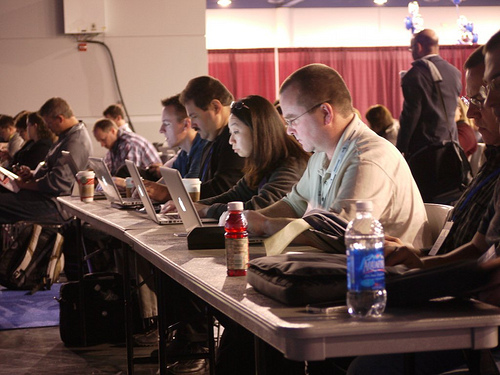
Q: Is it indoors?
A: Yes, it is indoors.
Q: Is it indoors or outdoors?
A: It is indoors.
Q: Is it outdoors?
A: No, it is indoors.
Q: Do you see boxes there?
A: No, there are no boxes.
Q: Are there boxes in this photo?
A: No, there are no boxes.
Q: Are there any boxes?
A: No, there are no boxes.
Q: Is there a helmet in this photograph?
A: No, there are no helmets.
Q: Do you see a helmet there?
A: No, there are no helmets.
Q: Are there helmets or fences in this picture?
A: No, there are no helmets or fences.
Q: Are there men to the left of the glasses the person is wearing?
A: Yes, there is a man to the left of the glasses.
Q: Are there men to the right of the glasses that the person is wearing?
A: No, the man is to the left of the glasses.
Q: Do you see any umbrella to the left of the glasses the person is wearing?
A: No, there is a man to the left of the glasses.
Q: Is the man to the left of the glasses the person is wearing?
A: Yes, the man is to the left of the glasses.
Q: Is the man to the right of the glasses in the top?
A: No, the man is to the left of the glasses.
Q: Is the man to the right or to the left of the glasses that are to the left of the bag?
A: The man is to the left of the glasses.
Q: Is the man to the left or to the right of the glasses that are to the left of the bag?
A: The man is to the left of the glasses.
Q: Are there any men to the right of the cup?
A: Yes, there is a man to the right of the cup.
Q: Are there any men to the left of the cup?
A: No, the man is to the right of the cup.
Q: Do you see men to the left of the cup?
A: No, the man is to the right of the cup.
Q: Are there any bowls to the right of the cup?
A: No, there is a man to the right of the cup.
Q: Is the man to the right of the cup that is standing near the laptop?
A: Yes, the man is to the right of the cup.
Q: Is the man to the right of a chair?
A: No, the man is to the right of the cup.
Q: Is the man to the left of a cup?
A: No, the man is to the right of a cup.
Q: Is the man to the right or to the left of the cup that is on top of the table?
A: The man is to the right of the cup.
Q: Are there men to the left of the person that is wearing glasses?
A: Yes, there is a man to the left of the person.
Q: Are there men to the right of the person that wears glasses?
A: No, the man is to the left of the person.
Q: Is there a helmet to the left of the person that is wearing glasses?
A: No, there is a man to the left of the person.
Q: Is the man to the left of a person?
A: Yes, the man is to the left of a person.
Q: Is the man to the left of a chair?
A: No, the man is to the left of a person.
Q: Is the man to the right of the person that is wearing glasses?
A: No, the man is to the left of the person.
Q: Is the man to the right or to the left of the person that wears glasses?
A: The man is to the left of the person.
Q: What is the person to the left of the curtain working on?
A: The man is working on a laptop.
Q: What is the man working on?
A: The man is working on a laptop.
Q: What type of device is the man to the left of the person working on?
A: The man is working on a laptop.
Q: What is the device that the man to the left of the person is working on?
A: The device is a laptop.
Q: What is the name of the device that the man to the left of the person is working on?
A: The device is a laptop.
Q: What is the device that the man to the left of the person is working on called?
A: The device is a laptop.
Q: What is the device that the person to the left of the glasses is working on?
A: The device is a laptop.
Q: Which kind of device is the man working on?
A: The man is working on a laptop.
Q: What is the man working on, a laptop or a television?
A: The man is working on a laptop.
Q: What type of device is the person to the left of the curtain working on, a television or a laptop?
A: The man is working on a laptop.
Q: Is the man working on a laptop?
A: Yes, the man is working on a laptop.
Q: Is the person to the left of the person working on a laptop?
A: Yes, the man is working on a laptop.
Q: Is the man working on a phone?
A: No, the man is working on a laptop.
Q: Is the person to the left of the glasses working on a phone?
A: No, the man is working on a laptop.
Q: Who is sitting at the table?
A: The man is sitting at the table.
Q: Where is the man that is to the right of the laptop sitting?
A: The man is sitting at the table.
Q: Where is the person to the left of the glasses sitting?
A: The man is sitting at the table.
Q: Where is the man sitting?
A: The man is sitting at the table.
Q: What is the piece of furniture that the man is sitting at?
A: The piece of furniture is a table.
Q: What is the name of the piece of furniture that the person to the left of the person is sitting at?
A: The piece of furniture is a table.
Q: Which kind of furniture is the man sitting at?
A: The man is sitting at the table.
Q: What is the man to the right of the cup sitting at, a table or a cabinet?
A: The man is sitting at a table.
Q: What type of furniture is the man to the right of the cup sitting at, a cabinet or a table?
A: The man is sitting at a table.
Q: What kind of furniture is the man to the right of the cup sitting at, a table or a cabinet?
A: The man is sitting at a table.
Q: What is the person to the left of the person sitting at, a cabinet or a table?
A: The man is sitting at a table.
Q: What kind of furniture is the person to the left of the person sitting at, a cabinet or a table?
A: The man is sitting at a table.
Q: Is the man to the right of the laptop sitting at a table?
A: Yes, the man is sitting at a table.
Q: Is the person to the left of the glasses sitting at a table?
A: Yes, the man is sitting at a table.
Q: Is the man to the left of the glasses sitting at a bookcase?
A: No, the man is sitting at a table.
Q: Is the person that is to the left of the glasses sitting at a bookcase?
A: No, the man is sitting at a table.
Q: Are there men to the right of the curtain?
A: No, the man is to the left of the curtain.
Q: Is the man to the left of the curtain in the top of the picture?
A: Yes, the man is to the left of the curtain.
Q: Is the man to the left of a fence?
A: No, the man is to the left of the curtain.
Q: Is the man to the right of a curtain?
A: No, the man is to the left of a curtain.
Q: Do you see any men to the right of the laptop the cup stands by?
A: Yes, there is a man to the right of the laptop.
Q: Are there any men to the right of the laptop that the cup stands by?
A: Yes, there is a man to the right of the laptop.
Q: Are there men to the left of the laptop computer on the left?
A: No, the man is to the right of the laptop.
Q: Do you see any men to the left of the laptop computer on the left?
A: No, the man is to the right of the laptop.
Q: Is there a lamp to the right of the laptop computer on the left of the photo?
A: No, there is a man to the right of the laptop.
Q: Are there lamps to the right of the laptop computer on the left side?
A: No, there is a man to the right of the laptop.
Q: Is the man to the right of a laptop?
A: Yes, the man is to the right of a laptop.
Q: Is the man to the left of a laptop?
A: No, the man is to the right of a laptop.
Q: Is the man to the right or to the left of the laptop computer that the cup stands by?
A: The man is to the right of the laptop.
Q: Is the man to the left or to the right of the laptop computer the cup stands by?
A: The man is to the right of the laptop.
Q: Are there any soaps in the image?
A: No, there are no soaps.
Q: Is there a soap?
A: No, there are no soaps.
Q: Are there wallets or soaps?
A: No, there are no soaps or wallets.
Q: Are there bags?
A: Yes, there is a bag.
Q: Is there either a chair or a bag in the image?
A: Yes, there is a bag.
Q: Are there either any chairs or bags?
A: Yes, there is a bag.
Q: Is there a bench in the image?
A: No, there are no benches.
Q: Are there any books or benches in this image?
A: No, there are no benches or books.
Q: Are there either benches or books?
A: No, there are no benches or books.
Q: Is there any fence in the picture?
A: No, there are no fences.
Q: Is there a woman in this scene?
A: Yes, there is a woman.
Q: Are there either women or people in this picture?
A: Yes, there is a woman.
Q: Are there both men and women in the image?
A: Yes, there are both a woman and a man.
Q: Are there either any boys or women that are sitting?
A: Yes, the woman is sitting.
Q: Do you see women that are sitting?
A: Yes, there is a woman that is sitting.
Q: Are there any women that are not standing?
A: Yes, there is a woman that is sitting.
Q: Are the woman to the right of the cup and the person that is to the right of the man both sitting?
A: Yes, both the woman and the person are sitting.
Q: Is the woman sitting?
A: Yes, the woman is sitting.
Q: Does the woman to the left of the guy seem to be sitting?
A: Yes, the woman is sitting.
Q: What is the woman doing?
A: The woman is sitting.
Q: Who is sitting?
A: The woman is sitting.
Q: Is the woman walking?
A: No, the woman is sitting.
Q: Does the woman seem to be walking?
A: No, the woman is sitting.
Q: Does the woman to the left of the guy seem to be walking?
A: No, the woman is sitting.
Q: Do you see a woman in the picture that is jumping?
A: No, there is a woman but she is sitting.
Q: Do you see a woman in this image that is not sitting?
A: No, there is a woman but she is sitting.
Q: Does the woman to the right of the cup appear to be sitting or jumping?
A: The woman is sitting.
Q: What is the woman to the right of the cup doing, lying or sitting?
A: The woman is sitting.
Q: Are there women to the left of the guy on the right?
A: Yes, there is a woman to the left of the guy.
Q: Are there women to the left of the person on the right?
A: Yes, there is a woman to the left of the guy.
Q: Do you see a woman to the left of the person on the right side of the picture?
A: Yes, there is a woman to the left of the guy.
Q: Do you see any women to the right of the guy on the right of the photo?
A: No, the woman is to the left of the guy.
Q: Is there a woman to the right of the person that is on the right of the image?
A: No, the woman is to the left of the guy.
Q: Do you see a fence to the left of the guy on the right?
A: No, there is a woman to the left of the guy.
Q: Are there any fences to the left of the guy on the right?
A: No, there is a woman to the left of the guy.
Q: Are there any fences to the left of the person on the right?
A: No, there is a woman to the left of the guy.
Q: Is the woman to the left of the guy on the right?
A: Yes, the woman is to the left of the guy.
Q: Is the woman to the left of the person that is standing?
A: Yes, the woman is to the left of the guy.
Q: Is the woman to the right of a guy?
A: No, the woman is to the left of a guy.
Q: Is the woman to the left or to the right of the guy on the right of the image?
A: The woman is to the left of the guy.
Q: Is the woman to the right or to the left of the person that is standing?
A: The woman is to the left of the guy.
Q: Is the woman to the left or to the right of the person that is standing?
A: The woman is to the left of the guy.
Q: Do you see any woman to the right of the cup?
A: Yes, there is a woman to the right of the cup.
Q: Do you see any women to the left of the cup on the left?
A: No, the woman is to the right of the cup.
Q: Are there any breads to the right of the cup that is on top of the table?
A: No, there is a woman to the right of the cup.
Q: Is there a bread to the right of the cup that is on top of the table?
A: No, there is a woman to the right of the cup.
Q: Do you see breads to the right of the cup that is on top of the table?
A: No, there is a woman to the right of the cup.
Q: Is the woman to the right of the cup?
A: Yes, the woman is to the right of the cup.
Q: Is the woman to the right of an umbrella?
A: No, the woman is to the right of the cup.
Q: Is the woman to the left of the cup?
A: No, the woman is to the right of the cup.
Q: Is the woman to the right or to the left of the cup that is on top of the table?
A: The woman is to the right of the cup.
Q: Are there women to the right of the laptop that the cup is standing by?
A: Yes, there is a woman to the right of the laptop.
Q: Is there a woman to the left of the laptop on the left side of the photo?
A: No, the woman is to the right of the laptop.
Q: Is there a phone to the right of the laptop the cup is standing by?
A: No, there is a woman to the right of the laptop.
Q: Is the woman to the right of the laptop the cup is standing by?
A: Yes, the woman is to the right of the laptop computer.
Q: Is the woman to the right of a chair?
A: No, the woman is to the right of the laptop computer.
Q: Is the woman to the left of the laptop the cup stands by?
A: No, the woman is to the right of the laptop computer.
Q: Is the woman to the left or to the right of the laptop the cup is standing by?
A: The woman is to the right of the laptop.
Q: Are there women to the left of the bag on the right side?
A: Yes, there is a woman to the left of the bag.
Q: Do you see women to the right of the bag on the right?
A: No, the woman is to the left of the bag.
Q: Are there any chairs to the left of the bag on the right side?
A: No, there is a woman to the left of the bag.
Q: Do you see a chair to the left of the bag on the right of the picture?
A: No, there is a woman to the left of the bag.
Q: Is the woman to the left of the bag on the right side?
A: Yes, the woman is to the left of the bag.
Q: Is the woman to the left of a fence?
A: No, the woman is to the left of the bag.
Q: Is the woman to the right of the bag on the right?
A: No, the woman is to the left of the bag.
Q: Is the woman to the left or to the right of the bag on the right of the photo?
A: The woman is to the left of the bag.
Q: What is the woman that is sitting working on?
A: The woman is working on a laptop.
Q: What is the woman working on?
A: The woman is working on a laptop.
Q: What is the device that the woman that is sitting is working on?
A: The device is a laptop.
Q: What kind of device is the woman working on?
A: The woman is working on a laptop.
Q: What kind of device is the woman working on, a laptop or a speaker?
A: The woman is working on a laptop.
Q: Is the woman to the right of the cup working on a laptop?
A: Yes, the woman is working on a laptop.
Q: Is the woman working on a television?
A: No, the woman is working on a laptop.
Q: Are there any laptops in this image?
A: Yes, there is a laptop.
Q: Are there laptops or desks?
A: Yes, there is a laptop.